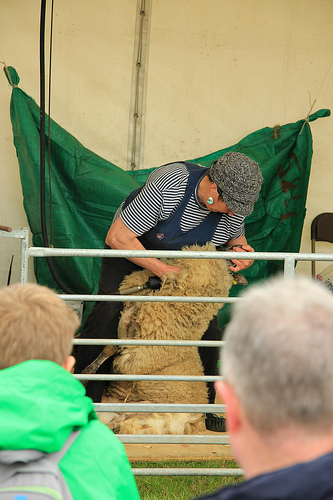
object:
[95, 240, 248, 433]
sheep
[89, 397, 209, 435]
wool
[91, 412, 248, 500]
ground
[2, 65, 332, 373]
tarp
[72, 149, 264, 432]
woman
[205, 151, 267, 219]
hat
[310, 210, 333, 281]
chair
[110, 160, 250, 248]
shirt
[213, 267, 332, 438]
hair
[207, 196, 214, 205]
earring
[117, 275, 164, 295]
shear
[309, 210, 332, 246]
part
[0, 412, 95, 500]
backpack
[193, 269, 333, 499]
man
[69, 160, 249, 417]
overalls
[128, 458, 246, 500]
grass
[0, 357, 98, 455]
hood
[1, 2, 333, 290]
wall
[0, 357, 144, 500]
jacket